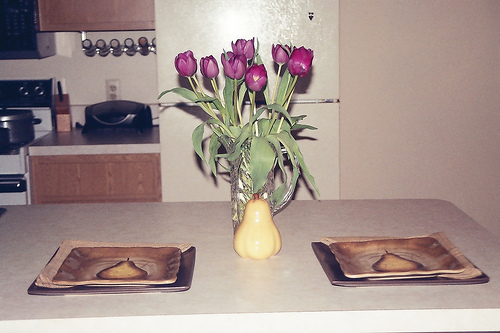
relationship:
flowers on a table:
[166, 23, 321, 264] [3, 193, 499, 331]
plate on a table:
[25, 237, 198, 299] [3, 193, 499, 331]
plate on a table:
[307, 226, 494, 296] [3, 193, 499, 331]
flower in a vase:
[242, 57, 276, 145] [218, 131, 289, 251]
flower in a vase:
[219, 47, 248, 133] [218, 131, 289, 251]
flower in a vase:
[267, 37, 293, 107] [218, 131, 289, 251]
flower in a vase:
[230, 33, 259, 61] [218, 131, 289, 251]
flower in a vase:
[173, 47, 202, 110] [218, 131, 289, 251]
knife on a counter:
[53, 77, 69, 105] [32, 101, 163, 154]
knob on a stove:
[33, 83, 46, 98] [1, 72, 57, 202]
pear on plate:
[91, 252, 150, 287] [25, 237, 198, 299]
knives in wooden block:
[53, 77, 69, 105] [50, 92, 78, 135]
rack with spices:
[78, 33, 158, 60] [84, 39, 155, 56]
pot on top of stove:
[3, 104, 40, 148] [1, 72, 57, 202]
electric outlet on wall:
[102, 77, 121, 103] [60, 34, 159, 105]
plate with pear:
[25, 237, 198, 299] [91, 252, 150, 287]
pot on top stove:
[3, 104, 40, 148] [1, 72, 57, 202]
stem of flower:
[172, 83, 212, 126] [168, 39, 204, 97]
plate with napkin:
[25, 237, 198, 299] [54, 244, 186, 286]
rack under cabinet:
[78, 33, 158, 60] [36, 2, 155, 31]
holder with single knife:
[50, 92, 78, 135] [53, 77, 69, 105]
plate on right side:
[307, 226, 494, 296] [447, 5, 499, 311]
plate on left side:
[25, 237, 198, 299] [3, 2, 35, 332]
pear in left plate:
[91, 252, 150, 287] [25, 237, 198, 299]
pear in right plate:
[368, 243, 429, 279] [307, 226, 494, 296]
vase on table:
[218, 131, 289, 251] [3, 193, 499, 331]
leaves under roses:
[155, 82, 322, 211] [166, 31, 318, 99]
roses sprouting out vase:
[166, 31, 318, 99] [218, 131, 289, 251]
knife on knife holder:
[53, 77, 69, 105] [50, 92, 78, 135]